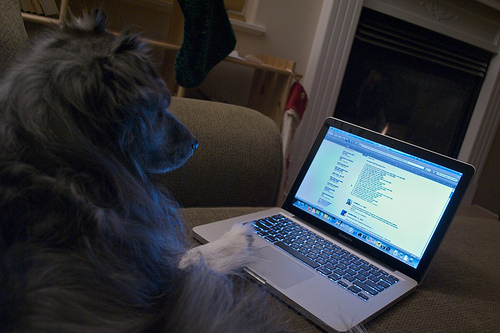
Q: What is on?
A: The laptop.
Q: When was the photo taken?
A: Nighttime.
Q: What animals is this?
A: Dog.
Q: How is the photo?
A: Clear.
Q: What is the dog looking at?
A: The laptop.